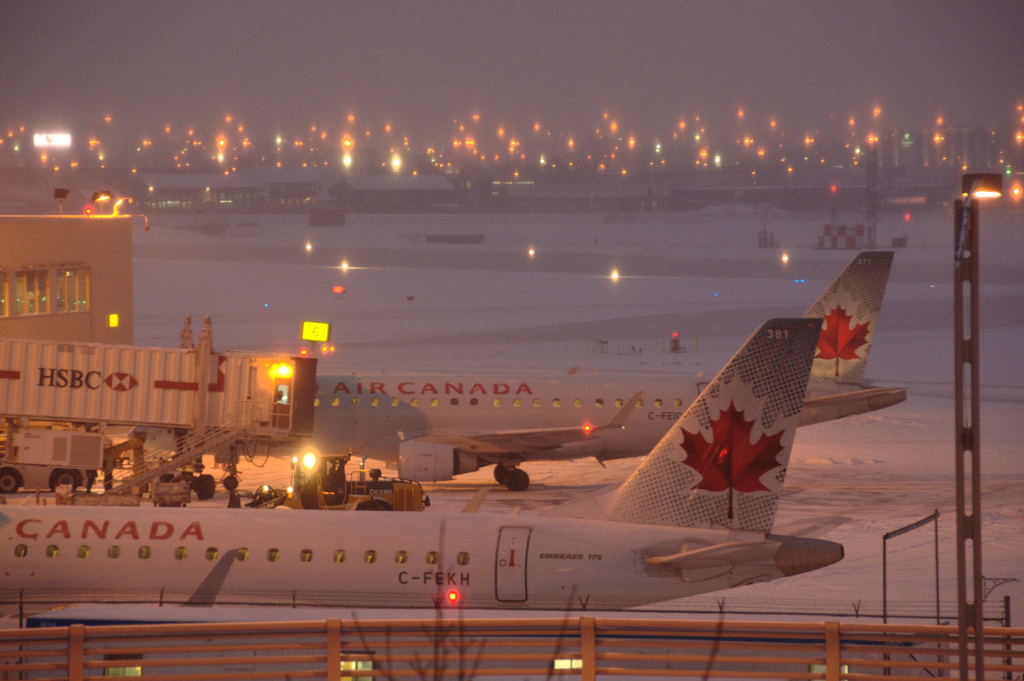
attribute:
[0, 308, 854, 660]
plane —  side 